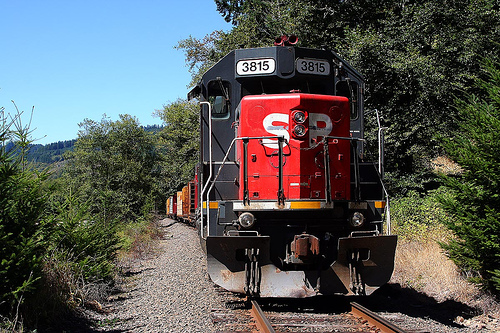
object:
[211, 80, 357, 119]
windshields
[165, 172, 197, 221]
train cars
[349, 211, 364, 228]
headlight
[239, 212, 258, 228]
headlight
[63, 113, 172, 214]
tree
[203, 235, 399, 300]
crossties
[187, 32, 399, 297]
engine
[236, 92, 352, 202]
structure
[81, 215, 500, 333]
gravel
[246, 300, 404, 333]
railroad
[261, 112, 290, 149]
letter s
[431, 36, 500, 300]
green tree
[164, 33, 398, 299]
train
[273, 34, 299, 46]
horn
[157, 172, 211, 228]
cars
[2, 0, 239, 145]
sky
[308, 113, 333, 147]
letter p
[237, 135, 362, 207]
metal railing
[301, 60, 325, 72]
number 3815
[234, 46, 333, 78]
top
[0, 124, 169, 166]
green hillside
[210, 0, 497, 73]
trees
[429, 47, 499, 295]
trees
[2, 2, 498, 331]
countryside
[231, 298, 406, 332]
rails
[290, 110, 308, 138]
headlight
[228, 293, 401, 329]
tracks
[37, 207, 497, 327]
hillside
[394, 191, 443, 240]
brush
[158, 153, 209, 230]
line